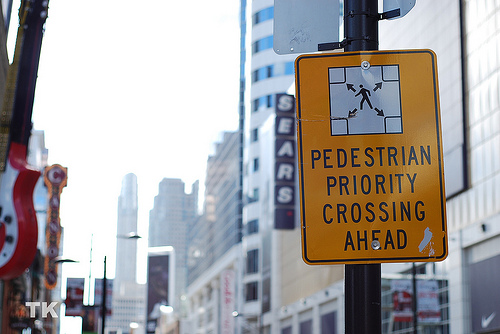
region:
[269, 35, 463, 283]
yellow and black pedestrian crossing sign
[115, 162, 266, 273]
blurry cityscape in the distance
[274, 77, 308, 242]
sears blue and white large sign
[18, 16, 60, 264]
red and white guitar sign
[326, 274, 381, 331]
black tall metal pole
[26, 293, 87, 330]
TK white logo in corner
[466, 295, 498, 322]
white nike sign on store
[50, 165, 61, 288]
red and yellow casino sign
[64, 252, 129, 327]
two rectangular flags hanging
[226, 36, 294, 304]
cylinder tall office building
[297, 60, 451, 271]
the sign is yellow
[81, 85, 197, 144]
the sky is white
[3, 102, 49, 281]
the guitar is red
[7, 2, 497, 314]
the scene is a city scene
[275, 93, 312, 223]
the sign has the word sears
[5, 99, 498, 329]
the photo was taken outdoors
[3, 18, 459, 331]
the scene was taken during the day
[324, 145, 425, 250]
the words are black in color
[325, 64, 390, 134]
the square is white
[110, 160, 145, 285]
the building is the tallest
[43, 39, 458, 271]
Picture taken during the day.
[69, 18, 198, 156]
The sky is white in color.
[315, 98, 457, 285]
A sign is on a pole.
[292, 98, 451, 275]
The sign is yellow, black and white.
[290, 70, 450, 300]
The sign says Pedestrian priority crossing ahead.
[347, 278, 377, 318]
The pole is black.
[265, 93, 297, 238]
The word SEARS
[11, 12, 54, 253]
A guitar is on the building.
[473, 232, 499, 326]
The NIKE logo is on the marquee.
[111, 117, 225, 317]
Tall buildings.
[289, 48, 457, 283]
pedestrian sign on pole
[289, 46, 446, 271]
yellow crossing sign at corner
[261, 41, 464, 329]
Sears store in background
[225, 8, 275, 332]
tall building in background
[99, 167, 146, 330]
skyscraper in the distance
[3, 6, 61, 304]
large guitar on left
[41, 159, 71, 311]
business sign on building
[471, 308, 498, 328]
Nike logo on window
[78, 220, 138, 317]
tall streetlamp on street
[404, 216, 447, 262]
paint scratch on yellow sign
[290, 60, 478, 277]
pedestrian priority crossing ahead sign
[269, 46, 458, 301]
a yellow sign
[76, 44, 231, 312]
the skyline in the background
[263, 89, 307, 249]
the sears sign in front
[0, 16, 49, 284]
a guitar sign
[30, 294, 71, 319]
the word TK in the picture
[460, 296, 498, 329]
Nike sign on the building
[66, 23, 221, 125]
cloudy in the background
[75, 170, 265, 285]
a group of skyscrapers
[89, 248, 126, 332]
a black pole in the photo